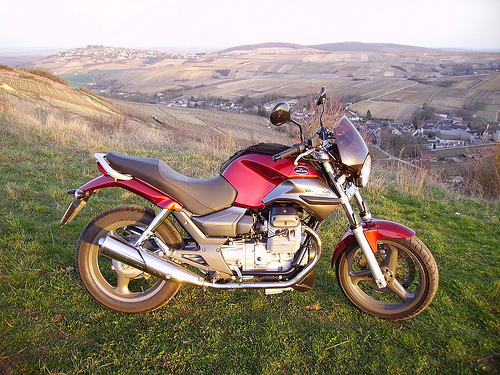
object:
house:
[430, 142, 500, 162]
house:
[404, 120, 415, 129]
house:
[408, 122, 429, 135]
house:
[390, 126, 404, 135]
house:
[188, 98, 200, 106]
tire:
[337, 236, 441, 322]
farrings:
[330, 115, 372, 189]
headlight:
[358, 152, 373, 189]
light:
[360, 153, 372, 189]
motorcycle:
[58, 84, 440, 322]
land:
[28, 45, 490, 152]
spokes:
[349, 267, 383, 286]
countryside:
[153, 96, 498, 162]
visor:
[333, 114, 370, 167]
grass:
[1, 295, 144, 368]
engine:
[219, 205, 322, 291]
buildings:
[366, 119, 414, 136]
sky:
[96, 0, 373, 71]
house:
[413, 126, 477, 148]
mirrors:
[269, 101, 292, 126]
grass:
[235, 307, 363, 358]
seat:
[106, 151, 238, 217]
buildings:
[390, 116, 468, 144]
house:
[434, 130, 462, 145]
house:
[384, 121, 406, 142]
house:
[202, 98, 235, 110]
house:
[432, 111, 448, 119]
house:
[217, 102, 237, 111]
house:
[220, 100, 237, 110]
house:
[185, 99, 201, 107]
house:
[154, 89, 164, 97]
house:
[117, 90, 124, 95]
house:
[365, 124, 382, 138]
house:
[428, 131, 468, 153]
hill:
[6, 36, 499, 76]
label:
[292, 166, 309, 175]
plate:
[60, 201, 74, 222]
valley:
[0, 40, 500, 372]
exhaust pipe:
[95, 225, 324, 291]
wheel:
[75, 204, 189, 316]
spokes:
[114, 275, 132, 295]